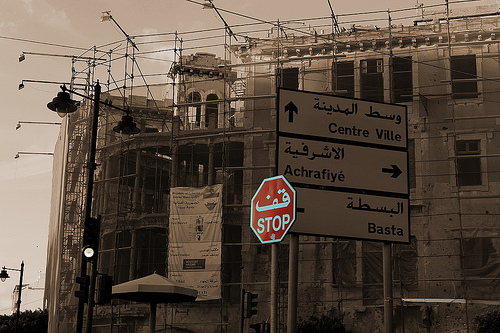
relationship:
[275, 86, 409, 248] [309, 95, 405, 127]
sign in arabic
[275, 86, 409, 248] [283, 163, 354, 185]
sign in roman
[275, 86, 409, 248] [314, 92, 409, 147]
sign printed in two alphabets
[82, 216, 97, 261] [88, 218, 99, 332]
traffic light on a pole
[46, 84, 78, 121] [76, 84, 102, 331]
streetlight on a pole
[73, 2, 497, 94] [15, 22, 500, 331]
scaffold on a building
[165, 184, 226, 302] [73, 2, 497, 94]
banner on scaffold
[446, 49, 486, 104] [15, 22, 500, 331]
window on building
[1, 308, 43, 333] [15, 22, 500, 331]
tree at rear of building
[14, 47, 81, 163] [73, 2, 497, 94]
lights attached to scaffold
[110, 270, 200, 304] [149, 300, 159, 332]
umbrella on a pole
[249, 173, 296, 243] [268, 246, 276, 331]
stop sign on a pole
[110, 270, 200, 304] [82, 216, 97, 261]
umbrella under traffic light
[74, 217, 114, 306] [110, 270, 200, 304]
traffic light by umbrella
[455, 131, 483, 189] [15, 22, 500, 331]
window on building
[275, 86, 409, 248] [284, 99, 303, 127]
sign with arrow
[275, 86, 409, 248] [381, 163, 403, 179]
sign with an arrow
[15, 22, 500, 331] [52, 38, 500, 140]
building on top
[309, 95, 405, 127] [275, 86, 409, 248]
arabic on sign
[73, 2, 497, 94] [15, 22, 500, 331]
scaffold around building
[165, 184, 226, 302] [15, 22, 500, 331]
banner hangs on building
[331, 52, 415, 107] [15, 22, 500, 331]
windows on a building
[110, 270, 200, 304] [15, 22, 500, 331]
umbrella below building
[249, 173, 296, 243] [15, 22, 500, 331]
stop sign below building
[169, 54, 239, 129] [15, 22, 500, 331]
tower on building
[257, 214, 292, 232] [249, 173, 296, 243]
stop on a stop sign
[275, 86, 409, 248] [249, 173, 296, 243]
sign next to stop sign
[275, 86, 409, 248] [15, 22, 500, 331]
sign in front of building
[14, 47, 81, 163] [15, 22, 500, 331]
lights on building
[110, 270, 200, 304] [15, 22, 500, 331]
umbrella in front of building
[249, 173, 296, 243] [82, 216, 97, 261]
stop sign by traffic light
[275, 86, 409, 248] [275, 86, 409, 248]
sign shows sign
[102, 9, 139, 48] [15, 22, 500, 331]
light over building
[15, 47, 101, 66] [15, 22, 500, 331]
light over building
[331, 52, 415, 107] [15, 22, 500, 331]
window on building